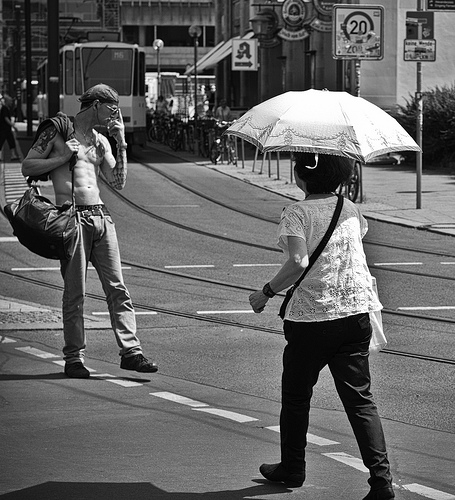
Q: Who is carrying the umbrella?
A: The people are carrying the umbrella.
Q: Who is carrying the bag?
A: The people are carrying the bag.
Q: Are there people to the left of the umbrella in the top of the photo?
A: Yes, there are people to the left of the umbrella.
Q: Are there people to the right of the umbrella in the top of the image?
A: No, the people are to the left of the umbrella.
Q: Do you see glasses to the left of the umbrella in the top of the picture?
A: No, there are people to the left of the umbrella.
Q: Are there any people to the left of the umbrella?
A: Yes, there are people to the left of the umbrella.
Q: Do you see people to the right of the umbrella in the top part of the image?
A: No, the people are to the left of the umbrella.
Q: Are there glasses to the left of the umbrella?
A: No, there are people to the left of the umbrella.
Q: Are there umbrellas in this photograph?
A: Yes, there is an umbrella.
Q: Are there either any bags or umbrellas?
A: Yes, there is an umbrella.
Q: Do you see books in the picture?
A: No, there are no books.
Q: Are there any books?
A: No, there are no books.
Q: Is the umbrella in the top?
A: Yes, the umbrella is in the top of the image.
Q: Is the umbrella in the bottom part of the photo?
A: No, the umbrella is in the top of the image.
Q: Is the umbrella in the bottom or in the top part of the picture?
A: The umbrella is in the top of the image.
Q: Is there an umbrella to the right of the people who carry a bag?
A: Yes, there is an umbrella to the right of the people.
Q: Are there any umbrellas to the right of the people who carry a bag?
A: Yes, there is an umbrella to the right of the people.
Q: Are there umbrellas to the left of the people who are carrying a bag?
A: No, the umbrella is to the right of the people.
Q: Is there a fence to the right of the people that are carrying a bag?
A: No, there is an umbrella to the right of the people.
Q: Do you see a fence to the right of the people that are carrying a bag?
A: No, there is an umbrella to the right of the people.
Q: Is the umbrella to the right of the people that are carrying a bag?
A: Yes, the umbrella is to the right of the people.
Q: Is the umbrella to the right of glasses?
A: No, the umbrella is to the right of the people.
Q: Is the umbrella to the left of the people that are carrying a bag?
A: No, the umbrella is to the right of the people.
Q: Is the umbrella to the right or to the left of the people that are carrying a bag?
A: The umbrella is to the right of the people.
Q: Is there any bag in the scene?
A: Yes, there is a bag.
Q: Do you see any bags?
A: Yes, there is a bag.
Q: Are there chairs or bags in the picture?
A: Yes, there is a bag.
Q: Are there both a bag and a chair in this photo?
A: No, there is a bag but no chairs.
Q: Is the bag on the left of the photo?
A: Yes, the bag is on the left of the image.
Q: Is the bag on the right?
A: No, the bag is on the left of the image.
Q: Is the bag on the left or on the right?
A: The bag is on the left of the image.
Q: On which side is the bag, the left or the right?
A: The bag is on the left of the image.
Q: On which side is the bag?
A: The bag is on the left of the image.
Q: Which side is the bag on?
A: The bag is on the left of the image.